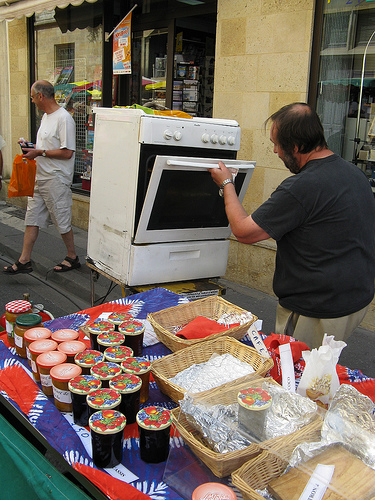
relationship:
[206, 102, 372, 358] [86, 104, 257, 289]
man inspecting oven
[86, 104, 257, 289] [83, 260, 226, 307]
oven on cart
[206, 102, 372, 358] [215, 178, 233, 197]
man wearing watch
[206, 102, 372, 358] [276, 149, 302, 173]
man has beard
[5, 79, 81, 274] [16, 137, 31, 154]
person holding wallet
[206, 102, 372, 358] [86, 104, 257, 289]
man opening oven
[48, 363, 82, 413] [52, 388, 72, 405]
jar has label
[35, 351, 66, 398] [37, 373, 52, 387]
jar has label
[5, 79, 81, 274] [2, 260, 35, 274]
person wearing sandal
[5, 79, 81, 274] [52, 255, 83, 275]
person wearing sandal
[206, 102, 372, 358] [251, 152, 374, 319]
man wearing shirt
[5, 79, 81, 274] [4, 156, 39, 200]
person carrying bag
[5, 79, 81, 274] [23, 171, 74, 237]
person wearing pants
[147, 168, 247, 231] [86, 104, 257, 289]
window on oven